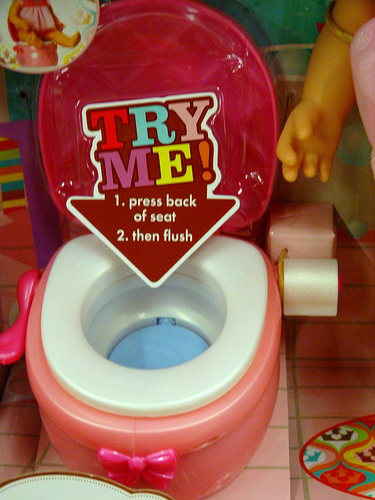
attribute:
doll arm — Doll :
[279, 0, 372, 183]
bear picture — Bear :
[7, 0, 80, 49]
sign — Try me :
[62, 88, 245, 293]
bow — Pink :
[97, 446, 175, 490]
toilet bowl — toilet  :
[1, 233, 282, 498]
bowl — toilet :
[40, 233, 267, 419]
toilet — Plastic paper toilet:
[5, 212, 331, 457]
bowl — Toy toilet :
[1, 7, 292, 491]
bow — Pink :
[93, 434, 180, 496]